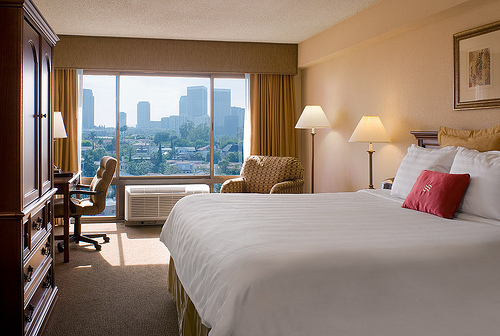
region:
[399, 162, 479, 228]
The red pillow on the bed.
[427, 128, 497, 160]
The yellow pillow on the bed.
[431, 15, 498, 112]
The art to the top of the headboard.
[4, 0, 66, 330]
The brown armoire in the room.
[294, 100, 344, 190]
The tallest lamp in the room.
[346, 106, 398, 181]
The lamp next to the tallest lamp.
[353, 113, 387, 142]
WHITE SHADE ON THE LAMP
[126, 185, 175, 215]
AIR CONDITION ON THE WALL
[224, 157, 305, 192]
CHAIR IN THE CORNER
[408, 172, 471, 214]
RED PILLOW ON THE BED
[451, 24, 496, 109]
PICTURE ON THE WALL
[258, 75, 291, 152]
CURTAINS UP TO THE WINDOW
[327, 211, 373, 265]
WHITE SHEET ON THE BED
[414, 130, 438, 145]
HEADBOARD MADE OUT OF WOOD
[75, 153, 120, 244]
OFFICE CHAIR AT THE DESK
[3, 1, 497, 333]
interior of hotel room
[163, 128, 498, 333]
bed with five pillows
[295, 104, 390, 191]
glowing shades on lamps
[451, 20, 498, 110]
square picture in frame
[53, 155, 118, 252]
computer chair on wheels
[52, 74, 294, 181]
windows with open curtains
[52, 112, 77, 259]
lamp on top of desk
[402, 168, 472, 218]
front of red pillow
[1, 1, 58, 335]
wood furniture with drawers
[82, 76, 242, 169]
view of city from window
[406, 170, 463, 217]
a red pillow on the bed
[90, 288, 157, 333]
the carpet is brown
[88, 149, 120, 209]
a chair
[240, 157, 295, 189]
a big chair next to the window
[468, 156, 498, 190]
a white pillow on the bed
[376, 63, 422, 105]
the wall is tanned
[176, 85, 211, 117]
tall buildings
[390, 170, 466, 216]
pillow on a bed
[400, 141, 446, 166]
pillow on a bed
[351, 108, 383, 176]
lamp near a bed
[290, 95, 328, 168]
lamp next to chair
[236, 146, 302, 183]
chair near a window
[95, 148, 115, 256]
chair next to desk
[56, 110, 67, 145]
lamp next to desk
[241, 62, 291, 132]
curtains on a window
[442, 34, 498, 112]
picture on a wall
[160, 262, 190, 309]
a bed skirt on the bed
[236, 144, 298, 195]
a chair next to the window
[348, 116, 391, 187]
used to brighten a room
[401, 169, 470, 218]
red item on the bed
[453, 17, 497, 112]
picture on the right wall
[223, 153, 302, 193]
beige item that can be sat on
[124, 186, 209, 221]
item used to change room temperature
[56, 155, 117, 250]
chair that can roll around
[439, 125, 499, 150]
item in back of white pillows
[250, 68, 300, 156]
item used to cover windows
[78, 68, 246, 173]
item used to look outside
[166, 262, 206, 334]
brown area on the bottom of the bed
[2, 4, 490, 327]
a clean hotel room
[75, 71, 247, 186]
view from a hotel room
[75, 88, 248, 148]
a city skyline through a window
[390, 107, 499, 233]
pillows stacked on a bed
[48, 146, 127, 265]
a chair pushed into a desk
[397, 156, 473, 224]
a small rectangular red pillow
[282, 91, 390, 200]
two lit floor lamps